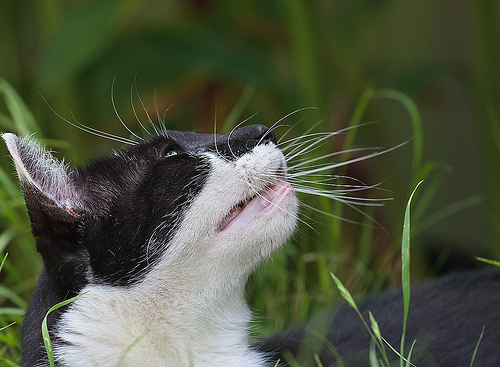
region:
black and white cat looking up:
[1, 116, 306, 361]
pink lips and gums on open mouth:
[212, 170, 287, 235]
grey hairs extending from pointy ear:
[0, 125, 82, 222]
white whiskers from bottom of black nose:
[205, 110, 411, 235]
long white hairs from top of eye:
[35, 57, 185, 138]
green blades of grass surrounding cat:
[2, 1, 427, 357]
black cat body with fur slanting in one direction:
[255, 257, 495, 357]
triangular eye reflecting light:
[155, 135, 177, 160]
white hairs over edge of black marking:
[137, 165, 192, 272]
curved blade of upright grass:
[397, 172, 423, 363]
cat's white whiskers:
[281, 113, 378, 225]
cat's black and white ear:
[3, 129, 79, 226]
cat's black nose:
[253, 123, 276, 143]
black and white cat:
[3, 117, 480, 364]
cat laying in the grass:
[0, 99, 495, 361]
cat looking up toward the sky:
[4, 116, 304, 361]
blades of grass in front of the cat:
[339, 175, 420, 363]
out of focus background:
[23, 8, 470, 108]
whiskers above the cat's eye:
[40, 74, 174, 142]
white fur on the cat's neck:
[171, 255, 240, 363]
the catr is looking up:
[0, 85, 412, 335]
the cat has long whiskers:
[81, 90, 194, 150]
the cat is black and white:
[2, 121, 373, 346]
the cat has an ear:
[5, 122, 110, 252]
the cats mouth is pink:
[95, 125, 380, 282]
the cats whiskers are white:
[62, 85, 419, 266]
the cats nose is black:
[190, 107, 300, 183]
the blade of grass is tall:
[345, 171, 440, 361]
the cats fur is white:
[130, 257, 227, 344]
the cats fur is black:
[106, 235, 123, 256]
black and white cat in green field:
[5, 102, 314, 365]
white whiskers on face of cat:
[207, 101, 419, 238]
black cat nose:
[235, 115, 279, 146]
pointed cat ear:
[2, 125, 93, 247]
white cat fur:
[175, 265, 227, 350]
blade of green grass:
[387, 165, 444, 364]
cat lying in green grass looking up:
[2, 115, 494, 364]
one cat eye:
[152, 136, 194, 166]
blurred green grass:
[4, 1, 498, 283]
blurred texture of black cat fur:
[427, 288, 490, 323]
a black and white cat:
[8, 92, 493, 365]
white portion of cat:
[51, 140, 311, 365]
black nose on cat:
[230, 115, 298, 152]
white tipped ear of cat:
[1, 125, 86, 222]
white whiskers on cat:
[210, 93, 424, 263]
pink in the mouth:
[216, 172, 311, 224]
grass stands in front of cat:
[308, 133, 465, 365]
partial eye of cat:
[161, 137, 204, 164]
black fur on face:
[48, 121, 216, 285]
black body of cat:
[257, 229, 498, 364]